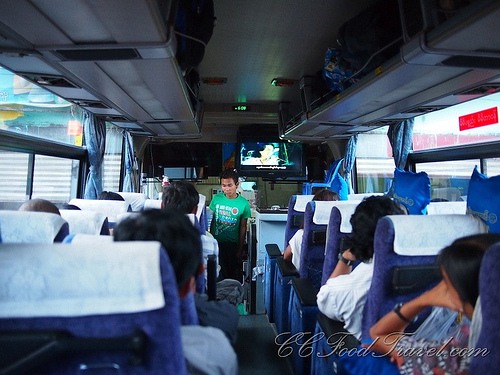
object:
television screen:
[239, 141, 303, 171]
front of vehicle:
[133, 125, 341, 208]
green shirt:
[208, 192, 252, 243]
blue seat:
[0, 241, 190, 375]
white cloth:
[0, 239, 167, 321]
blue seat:
[308, 214, 489, 375]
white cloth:
[385, 213, 492, 257]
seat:
[63, 197, 133, 237]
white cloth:
[312, 200, 363, 225]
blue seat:
[270, 200, 364, 346]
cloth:
[66, 197, 131, 223]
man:
[205, 168, 253, 286]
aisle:
[196, 312, 294, 374]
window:
[0, 147, 84, 205]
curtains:
[81, 108, 108, 201]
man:
[105, 204, 240, 375]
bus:
[0, 0, 500, 375]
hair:
[161, 180, 200, 214]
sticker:
[457, 106, 499, 131]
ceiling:
[194, 0, 373, 104]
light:
[232, 104, 250, 111]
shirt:
[313, 251, 378, 342]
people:
[316, 195, 411, 344]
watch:
[337, 250, 358, 266]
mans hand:
[342, 244, 361, 261]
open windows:
[0, 66, 86, 150]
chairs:
[263, 194, 339, 324]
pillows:
[384, 166, 432, 216]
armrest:
[275, 256, 299, 277]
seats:
[56, 208, 111, 236]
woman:
[360, 231, 500, 375]